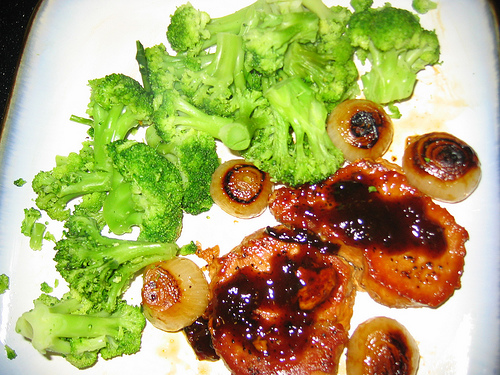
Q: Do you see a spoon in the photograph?
A: No, there are no spoons.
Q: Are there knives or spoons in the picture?
A: No, there are no spoons or knives.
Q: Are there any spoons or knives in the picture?
A: No, there are no spoons or knives.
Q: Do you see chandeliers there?
A: No, there are no chandeliers.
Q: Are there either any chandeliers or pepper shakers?
A: No, there are no chandeliers or pepper shakers.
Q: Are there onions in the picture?
A: Yes, there is an onion.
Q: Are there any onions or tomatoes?
A: Yes, there is an onion.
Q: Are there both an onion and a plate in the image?
A: Yes, there are both an onion and a plate.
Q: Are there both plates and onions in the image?
A: Yes, there are both an onion and a plate.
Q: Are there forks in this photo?
A: No, there are no forks.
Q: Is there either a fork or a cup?
A: No, there are no forks or cups.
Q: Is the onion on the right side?
A: Yes, the onion is on the right of the image.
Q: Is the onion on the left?
A: No, the onion is on the right of the image.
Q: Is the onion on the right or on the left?
A: The onion is on the right of the image.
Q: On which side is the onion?
A: The onion is on the right of the image.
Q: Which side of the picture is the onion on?
A: The onion is on the right of the image.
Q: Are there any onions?
A: Yes, there is an onion.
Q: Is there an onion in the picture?
A: Yes, there is an onion.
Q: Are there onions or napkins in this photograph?
A: Yes, there is an onion.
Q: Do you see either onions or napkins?
A: Yes, there is an onion.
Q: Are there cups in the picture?
A: No, there are no cups.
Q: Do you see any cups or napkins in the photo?
A: No, there are no cups or napkins.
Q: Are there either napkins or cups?
A: No, there are no cups or napkins.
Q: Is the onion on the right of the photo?
A: Yes, the onion is on the right of the image.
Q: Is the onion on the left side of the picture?
A: No, the onion is on the right of the image.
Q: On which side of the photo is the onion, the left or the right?
A: The onion is on the right of the image.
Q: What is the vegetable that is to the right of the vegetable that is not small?
A: The vegetable is an onion.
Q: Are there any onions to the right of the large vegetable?
A: Yes, there is an onion to the right of the vegetable.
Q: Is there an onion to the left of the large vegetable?
A: No, the onion is to the right of the vegetable.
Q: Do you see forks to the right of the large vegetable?
A: No, there is an onion to the right of the vegetable.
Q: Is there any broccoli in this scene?
A: Yes, there is broccoli.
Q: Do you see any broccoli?
A: Yes, there is broccoli.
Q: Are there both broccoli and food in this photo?
A: Yes, there are both broccoli and food.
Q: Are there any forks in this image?
A: No, there are no forks.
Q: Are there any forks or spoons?
A: No, there are no forks or spoons.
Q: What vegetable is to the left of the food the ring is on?
A: The vegetable is broccoli.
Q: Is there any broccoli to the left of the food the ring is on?
A: Yes, there is broccoli to the left of the food.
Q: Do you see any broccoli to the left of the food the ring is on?
A: Yes, there is broccoli to the left of the food.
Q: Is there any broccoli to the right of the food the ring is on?
A: No, the broccoli is to the left of the food.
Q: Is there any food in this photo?
A: Yes, there is food.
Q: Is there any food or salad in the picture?
A: Yes, there is food.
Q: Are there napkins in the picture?
A: No, there are no napkins.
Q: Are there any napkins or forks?
A: No, there are no napkins or forks.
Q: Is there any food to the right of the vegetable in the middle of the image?
A: Yes, there is food to the right of the vegetable.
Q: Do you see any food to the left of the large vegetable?
A: No, the food is to the right of the vegetable.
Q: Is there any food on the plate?
A: Yes, there is food on the plate.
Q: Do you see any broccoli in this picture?
A: Yes, there is broccoli.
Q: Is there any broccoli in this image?
A: Yes, there is broccoli.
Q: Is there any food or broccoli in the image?
A: Yes, there is broccoli.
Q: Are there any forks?
A: No, there are no forks.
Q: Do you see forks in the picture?
A: No, there are no forks.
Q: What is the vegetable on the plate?
A: The vegetable is broccoli.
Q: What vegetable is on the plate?
A: The vegetable is broccoli.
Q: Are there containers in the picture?
A: No, there are no containers.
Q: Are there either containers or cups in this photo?
A: No, there are no containers or cups.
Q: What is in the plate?
A: The sauce is in the plate.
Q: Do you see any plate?
A: Yes, there is a plate.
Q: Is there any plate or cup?
A: Yes, there is a plate.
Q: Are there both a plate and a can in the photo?
A: No, there is a plate but no cans.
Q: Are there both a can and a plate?
A: No, there is a plate but no cans.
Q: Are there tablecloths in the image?
A: No, there are no tablecloths.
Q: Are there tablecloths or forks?
A: No, there are no tablecloths or forks.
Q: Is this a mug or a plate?
A: This is a plate.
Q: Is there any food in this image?
A: Yes, there is food.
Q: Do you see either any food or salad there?
A: Yes, there is food.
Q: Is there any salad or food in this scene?
A: Yes, there is food.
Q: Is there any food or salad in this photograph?
A: Yes, there is food.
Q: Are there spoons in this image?
A: No, there are no spoons.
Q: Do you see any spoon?
A: No, there are no spoons.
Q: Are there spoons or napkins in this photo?
A: No, there are no spoons or napkins.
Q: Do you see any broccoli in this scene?
A: Yes, there is broccoli.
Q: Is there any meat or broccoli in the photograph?
A: Yes, there is broccoli.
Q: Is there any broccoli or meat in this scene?
A: Yes, there is broccoli.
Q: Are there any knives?
A: No, there are no knives.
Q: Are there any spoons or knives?
A: No, there are no knives or spoons.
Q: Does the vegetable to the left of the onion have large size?
A: Yes, the vegetable is large.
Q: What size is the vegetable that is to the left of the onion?
A: The vegetable is large.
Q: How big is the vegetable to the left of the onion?
A: The vegetable is large.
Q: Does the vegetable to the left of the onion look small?
A: No, the vegetable is large.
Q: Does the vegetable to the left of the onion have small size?
A: No, the vegetable is large.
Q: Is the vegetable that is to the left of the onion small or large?
A: The vegetable is large.